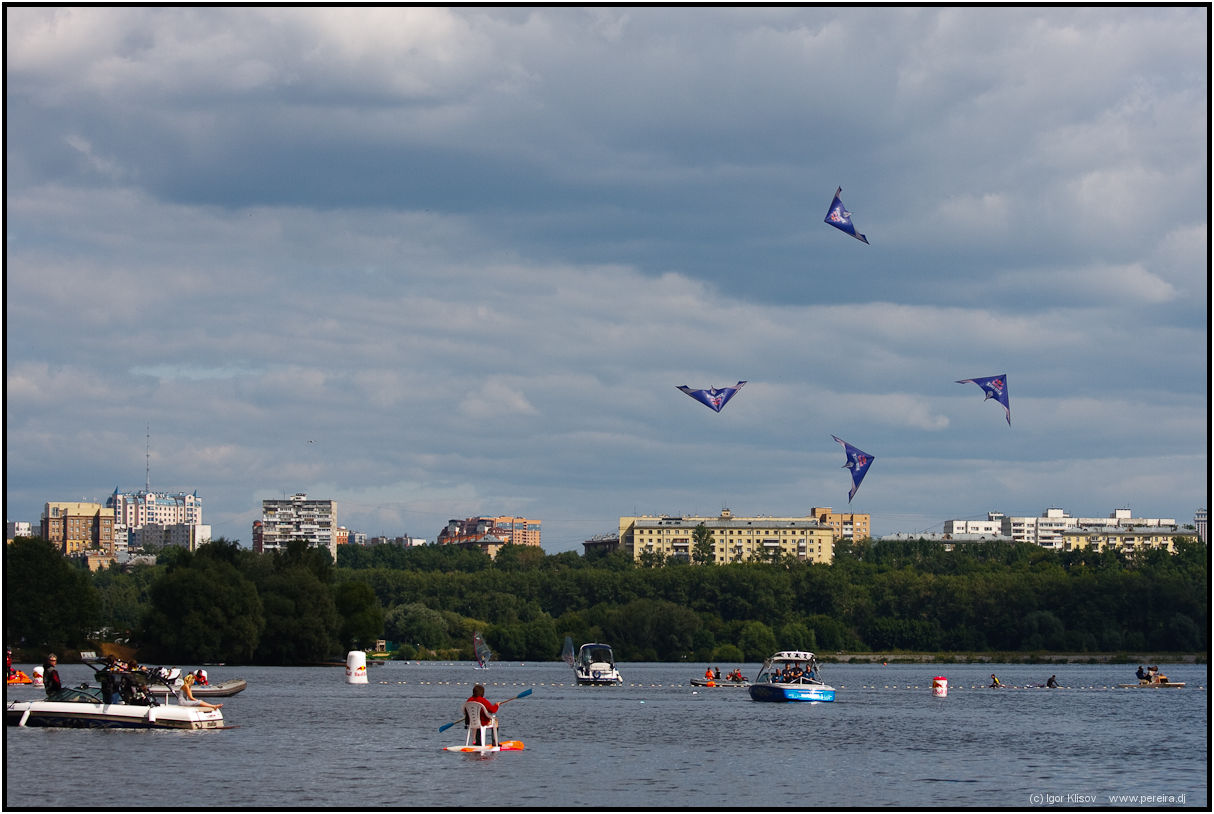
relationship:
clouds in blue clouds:
[75, 245, 732, 408] [0, 0, 1214, 560]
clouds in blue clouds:
[23, 13, 1124, 284] [0, 0, 1214, 560]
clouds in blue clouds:
[290, 339, 1159, 489] [0, 0, 1214, 560]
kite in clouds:
[674, 381, 747, 414] [0, 0, 1214, 560]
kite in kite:
[829, 435, 876, 506] [674, 381, 747, 414]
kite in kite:
[954, 373, 1012, 428] [674, 381, 747, 414]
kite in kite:
[824, 184, 871, 245] [674, 381, 747, 414]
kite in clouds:
[674, 366, 749, 414] [0, 0, 1214, 560]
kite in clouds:
[826, 426, 878, 505] [0, 0, 1214, 560]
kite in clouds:
[954, 361, 1022, 433] [0, 0, 1214, 560]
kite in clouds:
[817, 180, 876, 250] [0, 0, 1214, 560]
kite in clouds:
[828, 426, 880, 498] [0, 0, 1214, 560]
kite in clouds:
[669, 359, 755, 414] [0, 0, 1214, 560]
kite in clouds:
[956, 361, 1028, 425] [0, 0, 1214, 560]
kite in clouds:
[824, 184, 871, 245] [0, 0, 1214, 560]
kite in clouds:
[660, 357, 746, 416] [0, 0, 1214, 560]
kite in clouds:
[822, 430, 877, 505] [0, 0, 1214, 560]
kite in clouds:
[950, 370, 1020, 427] [0, 0, 1214, 560]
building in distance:
[245, 483, 348, 571] [45, 448, 1175, 534]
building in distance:
[618, 507, 835, 570] [45, 448, 1175, 534]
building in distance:
[42, 492, 123, 562] [45, 448, 1175, 534]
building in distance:
[102, 481, 210, 551] [45, 448, 1175, 534]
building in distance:
[435, 498, 538, 544] [45, 448, 1175, 534]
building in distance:
[250, 483, 347, 555] [25, 452, 1174, 549]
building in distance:
[429, 501, 550, 551] [25, 452, 1174, 549]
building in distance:
[618, 507, 835, 570] [25, 452, 1174, 549]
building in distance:
[40, 494, 123, 569] [25, 452, 1174, 549]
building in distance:
[98, 478, 212, 548] [25, 452, 1174, 549]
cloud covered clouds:
[0, 0, 498, 110] [0, 0, 1214, 560]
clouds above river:
[0, 0, 1214, 560] [4, 659, 1213, 809]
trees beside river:
[0, 536, 1209, 650] [12, 655, 1203, 796]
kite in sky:
[674, 381, 747, 414] [0, 6, 1200, 544]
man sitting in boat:
[463, 685, 500, 748] [439, 724, 531, 761]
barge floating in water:
[0, 682, 242, 730] [0, 644, 1209, 802]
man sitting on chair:
[456, 677, 495, 754] [463, 710, 504, 756]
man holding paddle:
[456, 677, 495, 754] [425, 721, 535, 767]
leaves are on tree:
[489, 558, 555, 628] [470, 538, 584, 657]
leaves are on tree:
[611, 545, 710, 611] [609, 538, 714, 624]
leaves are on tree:
[617, 611, 683, 650] [617, 598, 716, 670]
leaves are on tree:
[723, 609, 780, 648] [715, 585, 807, 664]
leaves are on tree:
[783, 569, 862, 617] [741, 538, 866, 657]